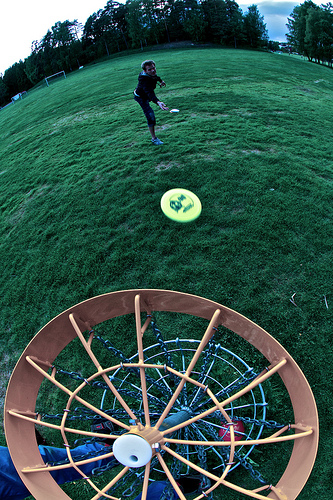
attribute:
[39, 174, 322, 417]
grass — lush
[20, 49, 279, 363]
grass — lush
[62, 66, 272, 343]
grass — lush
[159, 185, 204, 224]
frisbee — yellow, light green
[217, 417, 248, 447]
ball — pink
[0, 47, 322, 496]
grass — short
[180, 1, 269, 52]
bush — green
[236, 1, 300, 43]
cloud — white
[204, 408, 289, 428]
chains — gray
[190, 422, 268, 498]
chains — gray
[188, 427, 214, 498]
chains — gray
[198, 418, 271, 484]
chains — gray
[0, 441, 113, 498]
pant — purple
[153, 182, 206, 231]
frisbee — yellow